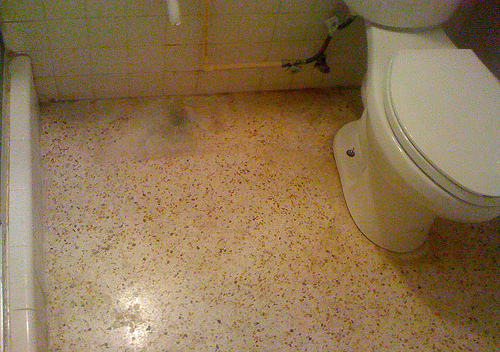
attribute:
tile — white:
[170, 45, 205, 82]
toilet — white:
[360, 30, 496, 201]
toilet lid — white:
[390, 44, 498, 214]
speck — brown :
[218, 247, 228, 255]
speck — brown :
[217, 245, 226, 254]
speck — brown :
[167, 230, 177, 236]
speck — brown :
[139, 217, 149, 228]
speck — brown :
[253, 221, 260, 231]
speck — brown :
[129, 240, 137, 249]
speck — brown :
[88, 248, 98, 258]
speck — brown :
[145, 325, 155, 333]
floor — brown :
[49, 79, 420, 350]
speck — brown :
[215, 318, 221, 326]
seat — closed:
[383, 49, 492, 202]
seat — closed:
[384, 44, 494, 213]